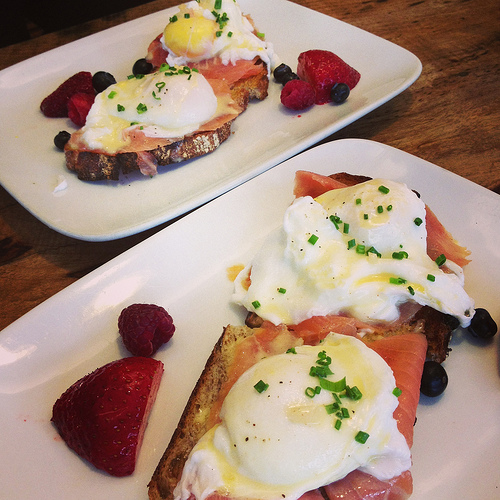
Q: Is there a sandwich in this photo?
A: Yes, there is a sandwich.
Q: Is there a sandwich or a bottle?
A: Yes, there is a sandwich.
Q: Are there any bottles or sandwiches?
A: Yes, there is a sandwich.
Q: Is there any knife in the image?
A: No, there are no knives.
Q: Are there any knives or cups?
A: No, there are no knives or cups.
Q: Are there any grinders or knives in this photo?
A: No, there are no knives or grinders.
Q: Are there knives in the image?
A: No, there are no knives.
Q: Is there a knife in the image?
A: No, there are no knives.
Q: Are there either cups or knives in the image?
A: No, there are no knives or cups.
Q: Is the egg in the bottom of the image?
A: Yes, the egg is in the bottom of the image.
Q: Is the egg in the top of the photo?
A: No, the egg is in the bottom of the image.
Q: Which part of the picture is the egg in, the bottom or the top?
A: The egg is in the bottom of the image.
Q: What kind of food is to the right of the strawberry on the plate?
A: The food is an egg.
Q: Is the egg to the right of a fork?
A: No, the egg is to the right of the strawberry.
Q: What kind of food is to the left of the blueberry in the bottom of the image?
A: The food is an egg.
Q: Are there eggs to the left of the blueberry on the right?
A: Yes, there is an egg to the left of the blueberry.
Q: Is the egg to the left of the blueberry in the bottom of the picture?
A: Yes, the egg is to the left of the blueberry.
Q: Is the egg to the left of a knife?
A: No, the egg is to the left of the blueberry.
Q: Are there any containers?
A: No, there are no containers.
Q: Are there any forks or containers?
A: No, there are no containers or forks.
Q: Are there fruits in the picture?
A: Yes, there is a fruit.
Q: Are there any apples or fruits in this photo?
A: Yes, there is a fruit.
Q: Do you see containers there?
A: No, there are no containers.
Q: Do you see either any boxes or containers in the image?
A: No, there are no containers or boxes.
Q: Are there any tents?
A: No, there are no tents.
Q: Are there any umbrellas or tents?
A: No, there are no tents or umbrellas.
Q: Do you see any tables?
A: Yes, there is a table.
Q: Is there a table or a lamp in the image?
A: Yes, there is a table.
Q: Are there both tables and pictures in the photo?
A: No, there is a table but no pictures.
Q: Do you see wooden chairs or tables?
A: Yes, there is a wood table.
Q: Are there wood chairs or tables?
A: Yes, there is a wood table.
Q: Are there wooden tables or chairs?
A: Yes, there is a wood table.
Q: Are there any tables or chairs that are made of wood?
A: Yes, the table is made of wood.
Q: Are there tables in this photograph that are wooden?
A: Yes, there is a wood table.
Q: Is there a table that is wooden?
A: Yes, there is a table that is wooden.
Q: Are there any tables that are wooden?
A: Yes, there is a table that is wooden.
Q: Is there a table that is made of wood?
A: Yes, there is a table that is made of wood.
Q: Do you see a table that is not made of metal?
A: Yes, there is a table that is made of wood.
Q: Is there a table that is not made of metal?
A: Yes, there is a table that is made of wood.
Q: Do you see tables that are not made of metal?
A: Yes, there is a table that is made of wood.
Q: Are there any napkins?
A: No, there are no napkins.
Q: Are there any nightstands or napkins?
A: No, there are no napkins or nightstands.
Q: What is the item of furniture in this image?
A: The piece of furniture is a table.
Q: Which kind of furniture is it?
A: The piece of furniture is a table.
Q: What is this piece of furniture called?
A: This is a table.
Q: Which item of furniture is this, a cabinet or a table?
A: This is a table.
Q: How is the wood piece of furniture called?
A: The piece of furniture is a table.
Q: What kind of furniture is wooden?
A: The furniture is a table.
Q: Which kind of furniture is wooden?
A: The furniture is a table.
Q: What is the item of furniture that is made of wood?
A: The piece of furniture is a table.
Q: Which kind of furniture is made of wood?
A: The furniture is a table.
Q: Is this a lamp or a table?
A: This is a table.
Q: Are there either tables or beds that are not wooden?
A: No, there is a table but it is wooden.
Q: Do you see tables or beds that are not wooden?
A: No, there is a table but it is wooden.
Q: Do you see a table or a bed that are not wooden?
A: No, there is a table but it is wooden.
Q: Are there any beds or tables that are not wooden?
A: No, there is a table but it is wooden.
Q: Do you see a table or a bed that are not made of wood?
A: No, there is a table but it is made of wood.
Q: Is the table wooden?
A: Yes, the table is wooden.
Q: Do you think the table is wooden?
A: Yes, the table is wooden.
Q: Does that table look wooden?
A: Yes, the table is wooden.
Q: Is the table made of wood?
A: Yes, the table is made of wood.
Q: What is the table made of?
A: The table is made of wood.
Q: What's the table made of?
A: The table is made of wood.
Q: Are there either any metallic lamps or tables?
A: No, there is a table but it is wooden.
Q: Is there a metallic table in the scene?
A: No, there is a table but it is wooden.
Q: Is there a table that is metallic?
A: No, there is a table but it is wooden.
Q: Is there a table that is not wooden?
A: No, there is a table but it is wooden.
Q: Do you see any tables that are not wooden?
A: No, there is a table but it is wooden.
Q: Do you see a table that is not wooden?
A: No, there is a table but it is wooden.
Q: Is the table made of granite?
A: No, the table is made of wood.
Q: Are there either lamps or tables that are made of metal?
A: No, there is a table but it is made of wood.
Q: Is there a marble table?
A: No, there is a table but it is made of wood.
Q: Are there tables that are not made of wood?
A: No, there is a table but it is made of wood.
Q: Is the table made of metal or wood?
A: The table is made of wood.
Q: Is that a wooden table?
A: Yes, that is a wooden table.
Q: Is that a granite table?
A: No, that is a wooden table.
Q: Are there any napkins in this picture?
A: No, there are no napkins.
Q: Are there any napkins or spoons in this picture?
A: No, there are no napkins or spoons.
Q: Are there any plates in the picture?
A: Yes, there is a plate.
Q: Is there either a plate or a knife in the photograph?
A: Yes, there is a plate.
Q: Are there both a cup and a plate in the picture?
A: No, there is a plate but no cups.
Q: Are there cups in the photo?
A: No, there are no cups.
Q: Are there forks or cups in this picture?
A: No, there are no cups or forks.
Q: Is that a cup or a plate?
A: That is a plate.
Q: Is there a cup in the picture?
A: No, there are no cups.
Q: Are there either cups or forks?
A: No, there are no cups or forks.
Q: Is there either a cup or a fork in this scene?
A: No, there are no cups or forks.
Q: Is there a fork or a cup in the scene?
A: No, there are no cups or forks.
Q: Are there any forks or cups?
A: No, there are no cups or forks.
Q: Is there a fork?
A: No, there are no forks.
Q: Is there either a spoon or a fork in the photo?
A: No, there are no forks or spoons.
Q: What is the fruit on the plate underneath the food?
A: The fruit is a raspberry.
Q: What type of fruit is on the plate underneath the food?
A: The fruit is a raspberry.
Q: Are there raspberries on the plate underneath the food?
A: Yes, there is a raspberry on the plate.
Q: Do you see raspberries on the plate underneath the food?
A: Yes, there is a raspberry on the plate.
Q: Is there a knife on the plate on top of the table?
A: No, there is a raspberry on the plate.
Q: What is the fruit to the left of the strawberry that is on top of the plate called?
A: The fruit is a raspberry.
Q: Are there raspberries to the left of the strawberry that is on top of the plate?
A: Yes, there is a raspberry to the left of the strawberry.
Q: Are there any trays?
A: No, there are no trays.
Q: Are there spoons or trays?
A: No, there are no trays or spoons.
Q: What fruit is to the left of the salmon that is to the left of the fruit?
A: The fruit is a blueberry.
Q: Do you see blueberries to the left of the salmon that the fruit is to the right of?
A: Yes, there is a blueberry to the left of the salmon.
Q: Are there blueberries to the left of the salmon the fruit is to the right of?
A: Yes, there is a blueberry to the left of the salmon.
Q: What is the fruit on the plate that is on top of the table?
A: The fruit is a blueberry.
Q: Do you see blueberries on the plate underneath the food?
A: Yes, there is a blueberry on the plate.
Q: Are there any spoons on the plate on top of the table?
A: No, there is a blueberry on the plate.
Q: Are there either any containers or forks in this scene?
A: No, there are no containers or forks.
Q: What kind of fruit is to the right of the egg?
A: The fruit is a blueberry.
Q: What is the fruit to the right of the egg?
A: The fruit is a blueberry.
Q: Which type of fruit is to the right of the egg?
A: The fruit is a blueberry.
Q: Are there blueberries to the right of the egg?
A: Yes, there is a blueberry to the right of the egg.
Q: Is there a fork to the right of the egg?
A: No, there is a blueberry to the right of the egg.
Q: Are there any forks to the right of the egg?
A: No, there is a blueberry to the right of the egg.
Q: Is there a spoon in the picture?
A: No, there are no spoons.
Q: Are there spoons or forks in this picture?
A: No, there are no spoons or forks.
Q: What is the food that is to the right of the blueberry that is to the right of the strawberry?
A: The food is salmon.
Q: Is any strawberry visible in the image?
A: Yes, there is a strawberry.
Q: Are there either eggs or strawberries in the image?
A: Yes, there is a strawberry.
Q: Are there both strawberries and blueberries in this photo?
A: Yes, there are both a strawberry and a blueberry.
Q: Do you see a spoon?
A: No, there are no spoons.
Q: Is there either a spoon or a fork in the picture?
A: No, there are no spoons or forks.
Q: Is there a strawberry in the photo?
A: Yes, there is a strawberry.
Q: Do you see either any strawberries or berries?
A: Yes, there is a strawberry.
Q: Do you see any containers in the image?
A: No, there are no containers.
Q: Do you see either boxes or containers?
A: No, there are no containers or boxes.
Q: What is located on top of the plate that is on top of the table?
A: The strawberry is on top of the plate.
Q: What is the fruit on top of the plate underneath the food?
A: The fruit is a strawberry.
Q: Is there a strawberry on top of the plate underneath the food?
A: Yes, there is a strawberry on top of the plate.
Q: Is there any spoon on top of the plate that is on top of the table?
A: No, there is a strawberry on top of the plate.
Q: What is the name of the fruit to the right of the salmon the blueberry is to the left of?
A: The fruit is a strawberry.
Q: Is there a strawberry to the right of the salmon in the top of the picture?
A: Yes, there is a strawberry to the right of the salmon.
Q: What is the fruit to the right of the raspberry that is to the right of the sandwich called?
A: The fruit is a strawberry.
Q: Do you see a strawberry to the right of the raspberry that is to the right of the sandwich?
A: Yes, there is a strawberry to the right of the raspberry.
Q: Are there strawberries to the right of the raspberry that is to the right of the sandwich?
A: Yes, there is a strawberry to the right of the raspberry.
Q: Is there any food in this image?
A: Yes, there is food.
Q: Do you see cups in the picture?
A: No, there are no cups.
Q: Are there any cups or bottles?
A: No, there are no cups or bottles.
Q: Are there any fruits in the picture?
A: Yes, there is a fruit.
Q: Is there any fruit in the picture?
A: Yes, there is a fruit.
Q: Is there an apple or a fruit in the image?
A: Yes, there is a fruit.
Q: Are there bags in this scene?
A: No, there are no bags.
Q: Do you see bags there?
A: No, there are no bags.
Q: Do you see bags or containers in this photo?
A: No, there are no bags or containers.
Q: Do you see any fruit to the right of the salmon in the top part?
A: Yes, there is a fruit to the right of the salmon.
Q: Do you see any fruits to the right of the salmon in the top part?
A: Yes, there is a fruit to the right of the salmon.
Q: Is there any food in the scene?
A: Yes, there is food.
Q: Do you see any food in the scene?
A: Yes, there is food.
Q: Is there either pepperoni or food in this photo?
A: Yes, there is food.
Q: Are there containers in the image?
A: No, there are no containers.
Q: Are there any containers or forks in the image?
A: No, there are no containers or forks.